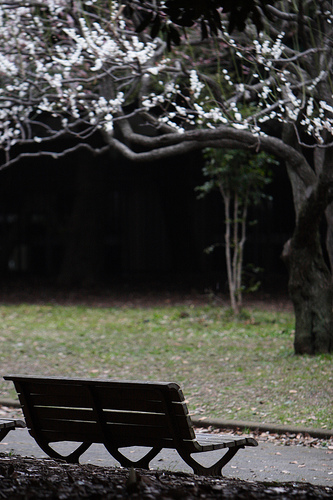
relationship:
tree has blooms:
[0, 3, 332, 354] [0, 0, 332, 150]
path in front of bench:
[1, 402, 328, 484] [2, 371, 276, 480]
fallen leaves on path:
[0, 453, 331, 497] [1, 402, 328, 484]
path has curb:
[1, 402, 328, 484] [1, 395, 331, 437]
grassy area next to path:
[0, 305, 333, 429] [1, 402, 328, 484]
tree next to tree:
[191, 138, 293, 314] [0, 3, 332, 354]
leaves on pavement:
[262, 431, 319, 444] [2, 401, 333, 484]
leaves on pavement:
[2, 300, 331, 430] [3, 402, 332, 497]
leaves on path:
[233, 423, 330, 460] [1, 402, 328, 484]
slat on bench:
[14, 406, 192, 426] [2, 371, 276, 480]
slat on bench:
[0, 371, 182, 398] [2, 371, 276, 480]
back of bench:
[0, 375, 193, 447] [2, 371, 276, 480]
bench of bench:
[1, 371, 258, 486] [7, 346, 264, 498]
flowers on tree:
[55, 20, 160, 70] [0, 3, 332, 354]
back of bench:
[59, 384, 142, 431] [118, 422, 226, 459]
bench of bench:
[1, 371, 258, 486] [5, 369, 265, 469]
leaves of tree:
[195, 149, 278, 205] [195, 38, 279, 312]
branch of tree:
[3, 139, 105, 168] [0, 3, 332, 354]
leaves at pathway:
[188, 333, 274, 352] [126, 420, 324, 481]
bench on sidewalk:
[1, 371, 260, 486] [28, 353, 332, 498]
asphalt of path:
[244, 446, 308, 480] [1, 402, 328, 484]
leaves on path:
[198, 421, 332, 450] [1, 402, 328, 484]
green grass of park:
[2, 302, 293, 381] [0, 80, 332, 424]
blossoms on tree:
[183, 68, 208, 108] [273, 85, 318, 329]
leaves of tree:
[192, 147, 278, 209] [0, 3, 332, 354]